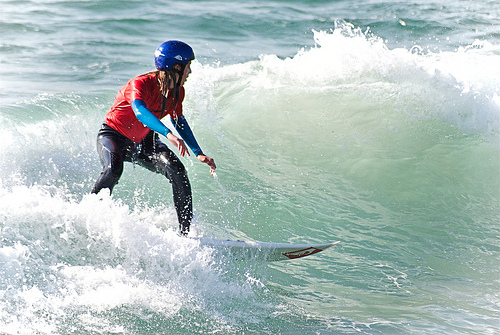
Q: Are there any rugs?
A: No, there are no rugs.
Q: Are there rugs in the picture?
A: No, there are no rugs.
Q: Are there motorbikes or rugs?
A: No, there are no rugs or motorbikes.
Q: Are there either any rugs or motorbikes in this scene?
A: No, there are no rugs or motorbikes.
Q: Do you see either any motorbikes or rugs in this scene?
A: No, there are no rugs or motorbikes.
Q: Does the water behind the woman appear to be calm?
A: Yes, the water is calm.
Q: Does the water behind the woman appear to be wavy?
A: No, the water is calm.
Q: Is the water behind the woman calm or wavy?
A: The water is calm.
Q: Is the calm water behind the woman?
A: Yes, the water is behind the woman.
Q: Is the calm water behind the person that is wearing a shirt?
A: Yes, the water is behind the woman.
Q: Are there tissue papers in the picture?
A: No, there are no tissue papers.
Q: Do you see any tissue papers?
A: No, there are no tissue papers.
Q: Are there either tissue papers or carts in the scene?
A: No, there are no tissue papers or carts.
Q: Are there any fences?
A: No, there are no fences.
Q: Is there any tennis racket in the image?
A: No, there are no rackets.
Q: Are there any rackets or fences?
A: No, there are no rackets or fences.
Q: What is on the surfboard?
A: The logo is on the surfboard.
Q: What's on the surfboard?
A: The logo is on the surfboard.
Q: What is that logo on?
A: The logo is on the surf board.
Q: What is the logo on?
A: The logo is on the surf board.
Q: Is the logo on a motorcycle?
A: No, the logo is on the surfboard.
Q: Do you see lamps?
A: No, there are no lamps.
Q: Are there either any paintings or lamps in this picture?
A: No, there are no lamps or paintings.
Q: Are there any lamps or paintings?
A: No, there are no lamps or paintings.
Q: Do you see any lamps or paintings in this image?
A: No, there are no lamps or paintings.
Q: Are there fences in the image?
A: No, there are no fences.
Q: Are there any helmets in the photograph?
A: Yes, there is a helmet.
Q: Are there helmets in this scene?
A: Yes, there is a helmet.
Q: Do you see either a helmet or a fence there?
A: Yes, there is a helmet.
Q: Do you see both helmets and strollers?
A: No, there is a helmet but no strollers.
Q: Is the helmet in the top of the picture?
A: Yes, the helmet is in the top of the image.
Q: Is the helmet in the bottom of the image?
A: No, the helmet is in the top of the image.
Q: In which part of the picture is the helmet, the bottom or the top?
A: The helmet is in the top of the image.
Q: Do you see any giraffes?
A: No, there are no giraffes.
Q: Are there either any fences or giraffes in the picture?
A: No, there are no giraffes or fences.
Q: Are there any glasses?
A: No, there are no glasses.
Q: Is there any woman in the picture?
A: Yes, there is a woman.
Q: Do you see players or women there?
A: Yes, there is a woman.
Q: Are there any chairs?
A: No, there are no chairs.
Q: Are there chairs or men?
A: No, there are no chairs or men.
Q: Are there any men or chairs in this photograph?
A: No, there are no chairs or men.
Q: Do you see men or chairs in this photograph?
A: No, there are no chairs or men.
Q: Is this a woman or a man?
A: This is a woman.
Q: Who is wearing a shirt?
A: The woman is wearing a shirt.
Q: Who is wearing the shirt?
A: The woman is wearing a shirt.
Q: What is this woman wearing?
A: The woman is wearing a shirt.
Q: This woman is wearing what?
A: The woman is wearing a shirt.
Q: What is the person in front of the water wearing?
A: The woman is wearing a shirt.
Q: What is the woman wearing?
A: The woman is wearing a shirt.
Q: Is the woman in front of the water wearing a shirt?
A: Yes, the woman is wearing a shirt.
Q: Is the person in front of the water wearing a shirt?
A: Yes, the woman is wearing a shirt.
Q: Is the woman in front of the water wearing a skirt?
A: No, the woman is wearing a shirt.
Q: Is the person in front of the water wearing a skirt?
A: No, the woman is wearing a shirt.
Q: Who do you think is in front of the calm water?
A: The woman is in front of the water.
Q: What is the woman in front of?
A: The woman is in front of the water.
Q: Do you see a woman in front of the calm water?
A: Yes, there is a woman in front of the water.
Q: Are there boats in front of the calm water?
A: No, there is a woman in front of the water.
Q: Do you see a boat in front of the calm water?
A: No, there is a woman in front of the water.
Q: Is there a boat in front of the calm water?
A: No, there is a woman in front of the water.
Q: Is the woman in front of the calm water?
A: Yes, the woman is in front of the water.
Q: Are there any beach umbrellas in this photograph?
A: No, there are no beach umbrellas.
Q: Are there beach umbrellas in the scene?
A: No, there are no beach umbrellas.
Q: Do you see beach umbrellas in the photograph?
A: No, there are no beach umbrellas.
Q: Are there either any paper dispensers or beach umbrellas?
A: No, there are no beach umbrellas or paper dispensers.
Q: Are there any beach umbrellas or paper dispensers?
A: No, there are no beach umbrellas or paper dispensers.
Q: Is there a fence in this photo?
A: No, there are no fences.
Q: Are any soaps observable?
A: No, there are no soaps.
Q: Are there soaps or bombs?
A: No, there are no soaps or bombs.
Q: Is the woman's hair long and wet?
A: Yes, the hair is long and wet.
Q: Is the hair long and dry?
A: No, the hair is long but wet.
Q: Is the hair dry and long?
A: No, the hair is long but wet.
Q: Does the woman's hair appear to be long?
A: Yes, the hair is long.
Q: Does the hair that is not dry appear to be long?
A: Yes, the hair is long.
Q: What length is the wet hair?
A: The hair is long.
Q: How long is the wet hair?
A: The hair is long.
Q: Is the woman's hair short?
A: No, the hair is long.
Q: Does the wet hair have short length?
A: No, the hair is long.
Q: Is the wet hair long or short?
A: The hair is long.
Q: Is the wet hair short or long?
A: The hair is long.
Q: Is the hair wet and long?
A: Yes, the hair is wet and long.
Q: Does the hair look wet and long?
A: Yes, the hair is wet and long.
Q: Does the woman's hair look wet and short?
A: No, the hair is wet but long.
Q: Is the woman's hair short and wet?
A: No, the hair is wet but long.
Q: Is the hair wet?
A: Yes, the hair is wet.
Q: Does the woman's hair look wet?
A: Yes, the hair is wet.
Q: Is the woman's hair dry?
A: No, the hair is wet.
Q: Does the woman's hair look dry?
A: No, the hair is wet.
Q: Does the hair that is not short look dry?
A: No, the hair is wet.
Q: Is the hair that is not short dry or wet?
A: The hair is wet.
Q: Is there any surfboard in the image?
A: Yes, there is a surfboard.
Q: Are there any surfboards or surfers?
A: Yes, there is a surfboard.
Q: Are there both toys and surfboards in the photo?
A: No, there is a surfboard but no toys.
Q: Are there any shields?
A: No, there are no shields.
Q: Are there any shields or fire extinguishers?
A: No, there are no shields or fire extinguishers.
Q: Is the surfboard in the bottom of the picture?
A: Yes, the surfboard is in the bottom of the image.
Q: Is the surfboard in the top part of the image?
A: No, the surfboard is in the bottom of the image.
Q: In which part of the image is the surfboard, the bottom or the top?
A: The surfboard is in the bottom of the image.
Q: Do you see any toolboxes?
A: No, there are no toolboxes.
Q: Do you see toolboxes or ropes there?
A: No, there are no toolboxes or ropes.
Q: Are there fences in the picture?
A: No, there are no fences.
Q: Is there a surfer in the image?
A: Yes, there is a surfer.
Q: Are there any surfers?
A: Yes, there is a surfer.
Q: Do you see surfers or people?
A: Yes, there is a surfer.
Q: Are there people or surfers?
A: Yes, there is a surfer.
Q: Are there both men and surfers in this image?
A: No, there is a surfer but no men.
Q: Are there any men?
A: No, there are no men.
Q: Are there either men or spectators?
A: No, there are no men or spectators.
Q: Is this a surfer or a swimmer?
A: This is a surfer.